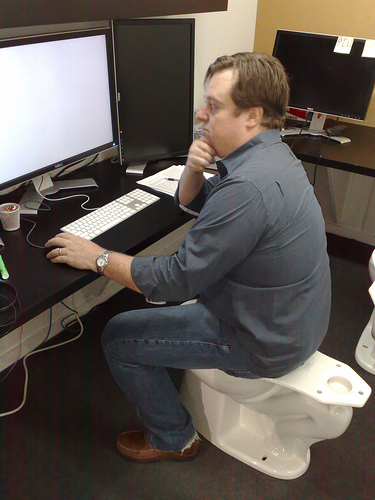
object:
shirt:
[131, 127, 333, 385]